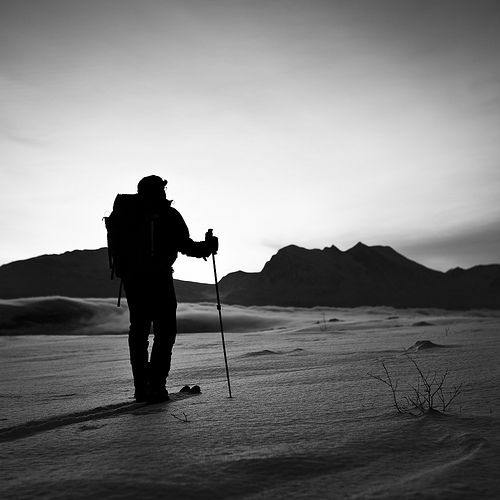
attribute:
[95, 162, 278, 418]
man — skiing, standing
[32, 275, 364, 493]
snow — white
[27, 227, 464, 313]
mountains — tall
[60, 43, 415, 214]
sky — clear